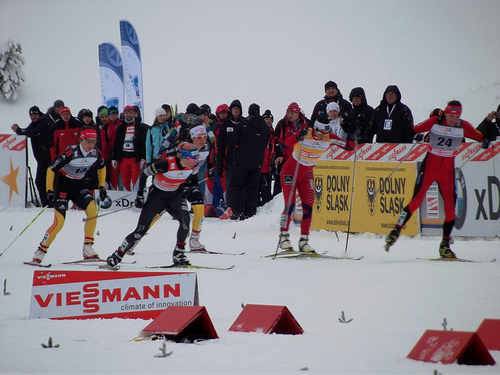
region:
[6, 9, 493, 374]
people are competing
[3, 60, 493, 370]
a competition of ski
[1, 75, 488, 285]
viewers behind the skiers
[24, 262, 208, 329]
a sign on the snow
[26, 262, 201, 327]
sign is white and red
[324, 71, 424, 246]
a yellow sign on front of viewers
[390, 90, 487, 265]
skier is number 24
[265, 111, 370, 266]
skier holds two snow poles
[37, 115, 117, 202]
skier wears a red headband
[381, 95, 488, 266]
skier wears a red suit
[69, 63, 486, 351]
people that are skiing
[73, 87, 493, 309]
people that are racing on skies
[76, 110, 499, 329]
people standing on skies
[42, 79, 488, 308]
people holding ski poles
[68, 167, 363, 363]
a ground covered in snow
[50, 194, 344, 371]
a ground covered in white snow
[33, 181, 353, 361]
snow covering the ground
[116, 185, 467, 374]
white snow covering the ground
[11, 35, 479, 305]
skiers that are racing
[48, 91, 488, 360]
skiers that are racing on the snow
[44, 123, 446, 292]
several skiers on a slope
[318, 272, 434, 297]
white snow of the ski slope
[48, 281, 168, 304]
red lettering on a white sign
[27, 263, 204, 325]
a red and white sign in the snow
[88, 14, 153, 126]
two blue and white banners behind the crowd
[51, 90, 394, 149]
several spectators behind the skiers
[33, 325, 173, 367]
two small plants growing out of the snow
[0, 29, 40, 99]
a snow covered tree behind the crowd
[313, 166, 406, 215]
black lettering on a yellow billdboard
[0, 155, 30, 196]
a yellow star on a white sign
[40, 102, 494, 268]
skiers racing down the hill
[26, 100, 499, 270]
skiers skiing in the snow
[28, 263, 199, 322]
red and white sign in the snow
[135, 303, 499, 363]
red signs in the snow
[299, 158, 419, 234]
yellow sign with black letters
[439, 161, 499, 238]
white advertisement for BMW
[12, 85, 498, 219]
group of people watching the skiers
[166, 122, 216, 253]
woman with a white headband on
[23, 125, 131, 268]
skier wearing yellow, black, and white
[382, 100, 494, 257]
skier wearing red and white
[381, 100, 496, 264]
a cross country skier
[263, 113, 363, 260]
a cross country skier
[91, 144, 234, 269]
a cross country skier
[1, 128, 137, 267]
a cross country skier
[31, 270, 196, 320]
a business promotional sign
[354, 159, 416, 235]
a business promotional sign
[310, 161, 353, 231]
a business promotional sign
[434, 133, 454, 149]
skier number 24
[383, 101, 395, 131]
a white lanyard name tag